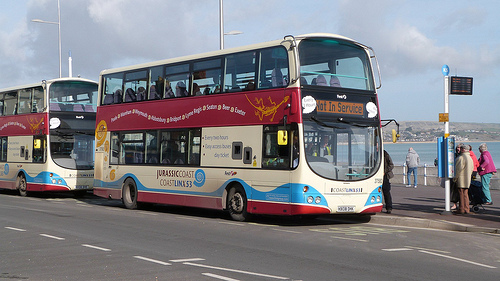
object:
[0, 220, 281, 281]
lines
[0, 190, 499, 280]
street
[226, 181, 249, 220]
wheel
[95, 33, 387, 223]
bus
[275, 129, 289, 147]
mirror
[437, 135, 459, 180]
sign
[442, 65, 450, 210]
pole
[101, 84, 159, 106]
seats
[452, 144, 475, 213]
man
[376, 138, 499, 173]
water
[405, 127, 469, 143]
houses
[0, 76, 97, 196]
bus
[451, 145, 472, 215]
people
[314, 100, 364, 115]
not in service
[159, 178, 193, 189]
company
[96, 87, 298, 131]
advertisement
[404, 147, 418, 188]
person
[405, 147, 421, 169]
hoodie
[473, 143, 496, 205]
lady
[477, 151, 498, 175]
jacket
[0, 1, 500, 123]
sky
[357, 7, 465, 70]
clouds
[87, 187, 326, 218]
stripe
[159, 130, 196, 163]
window